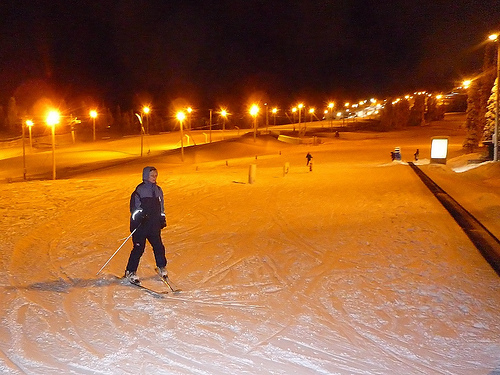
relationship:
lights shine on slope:
[24, 91, 447, 180] [1, 117, 500, 375]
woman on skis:
[126, 164, 169, 290] [108, 264, 183, 299]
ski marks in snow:
[2, 206, 496, 374] [2, 182, 498, 373]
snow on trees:
[382, 77, 500, 153] [379, 78, 500, 163]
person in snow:
[126, 164, 169, 290] [2, 182, 498, 373]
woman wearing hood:
[126, 164, 169, 290] [142, 165, 156, 182]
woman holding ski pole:
[126, 164, 169, 290] [96, 223, 146, 284]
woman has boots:
[126, 164, 169, 290] [125, 266, 169, 285]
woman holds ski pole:
[126, 164, 169, 290] [96, 223, 146, 284]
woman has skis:
[126, 164, 169, 290] [108, 264, 183, 299]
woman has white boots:
[126, 164, 169, 290] [125, 266, 169, 285]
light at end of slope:
[40, 110, 62, 180] [1, 117, 500, 375]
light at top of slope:
[40, 110, 62, 180] [1, 117, 500, 375]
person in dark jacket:
[305, 150, 313, 165] [306, 156, 312, 161]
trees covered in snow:
[379, 78, 500, 163] [382, 77, 500, 153]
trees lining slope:
[379, 78, 500, 163] [1, 117, 500, 375]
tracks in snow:
[2, 206, 496, 374] [2, 182, 498, 373]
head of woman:
[143, 166, 159, 183] [126, 164, 169, 290]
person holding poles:
[126, 164, 169, 290] [96, 223, 146, 284]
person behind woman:
[305, 150, 313, 165] [126, 164, 169, 290]